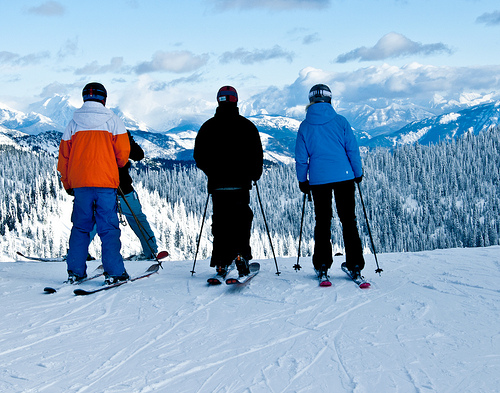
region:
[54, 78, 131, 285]
a man in orange in white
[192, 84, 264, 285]
a man in a black jacket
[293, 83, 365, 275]
woman in a blue jacket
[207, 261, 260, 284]
skis on a person's feet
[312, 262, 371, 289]
skis on a person's feet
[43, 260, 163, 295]
skis on a person's feet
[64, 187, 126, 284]
blue pants on a man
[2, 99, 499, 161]
mountains in the distance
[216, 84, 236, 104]
back of a helmet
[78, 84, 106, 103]
back of a helmet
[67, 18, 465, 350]
people skiing on the snow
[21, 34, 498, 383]
people skiing on the white snow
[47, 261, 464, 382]
a ground covered in snow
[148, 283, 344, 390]
ground covered in white snow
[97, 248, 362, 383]
snow covering the ground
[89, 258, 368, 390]
white snow covering the ground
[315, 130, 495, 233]
trees covered in snow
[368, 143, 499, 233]
trees covered in white snow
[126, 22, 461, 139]
a sky with clouds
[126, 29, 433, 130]
a blue sky with clouds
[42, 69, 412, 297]
four people at the top of a slope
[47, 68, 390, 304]
four people are skiing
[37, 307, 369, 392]
tracks in the snow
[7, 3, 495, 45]
the sky is blue and clear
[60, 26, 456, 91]
clouds in the sky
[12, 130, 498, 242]
trees in the valley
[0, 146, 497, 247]
the trees are covered in snow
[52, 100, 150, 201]
person wearing orange and white jacket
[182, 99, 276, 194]
person wearing black jacket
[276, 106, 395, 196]
the person wearing blue jacket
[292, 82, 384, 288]
skier looking over the slop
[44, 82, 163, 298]
skier preparing to ski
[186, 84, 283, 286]
skier looking at the mountain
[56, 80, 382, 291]
four skiers about to ski down the hill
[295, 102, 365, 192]
blue ski jacket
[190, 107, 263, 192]
black ski jacket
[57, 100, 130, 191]
white and orange ski jacket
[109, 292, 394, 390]
ski tracks in snow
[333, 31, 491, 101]
fluffy clouds on horizon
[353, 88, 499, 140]
mountains in the distance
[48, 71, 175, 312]
skier in snow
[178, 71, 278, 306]
skier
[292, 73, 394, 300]
skier in white snow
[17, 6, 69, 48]
white clouds in blue sky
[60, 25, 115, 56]
white clouds in blue sky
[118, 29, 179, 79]
white clouds in blue sky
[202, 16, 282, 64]
white clouds in blue sky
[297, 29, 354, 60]
white clouds in blue sky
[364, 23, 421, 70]
white clouds in blue sky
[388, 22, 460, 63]
white clouds in blue sky